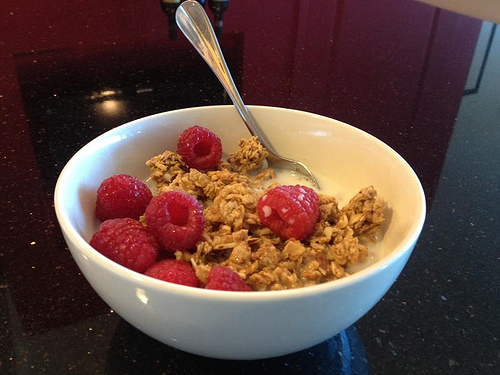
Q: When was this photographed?
A: Daytime.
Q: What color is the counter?
A: Black.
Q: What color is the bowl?
A: White.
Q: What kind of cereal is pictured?
A: Granola.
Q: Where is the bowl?
A: Counter.